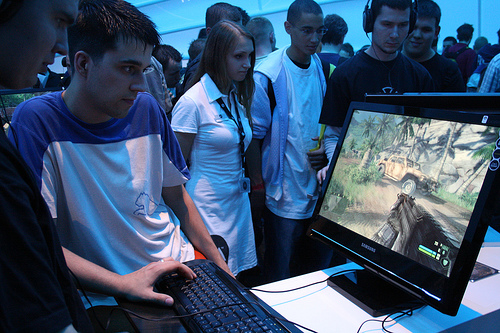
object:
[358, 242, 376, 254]
samsung logo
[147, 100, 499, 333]
computer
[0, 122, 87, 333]
black dress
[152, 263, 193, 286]
finger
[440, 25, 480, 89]
man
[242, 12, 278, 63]
man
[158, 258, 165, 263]
ring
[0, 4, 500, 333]
crowd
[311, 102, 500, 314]
video game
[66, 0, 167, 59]
hair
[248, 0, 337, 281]
people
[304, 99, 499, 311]
screen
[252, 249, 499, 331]
whitedesk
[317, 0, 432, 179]
boy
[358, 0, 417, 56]
head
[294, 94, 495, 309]
game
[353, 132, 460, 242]
fps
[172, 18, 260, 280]
girl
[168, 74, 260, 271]
dress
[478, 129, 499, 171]
stickers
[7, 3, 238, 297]
guy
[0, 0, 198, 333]
man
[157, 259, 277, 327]
keyboard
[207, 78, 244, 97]
neck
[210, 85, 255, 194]
tag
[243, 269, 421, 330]
wires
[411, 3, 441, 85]
person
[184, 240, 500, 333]
desk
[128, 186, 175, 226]
logo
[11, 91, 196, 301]
shirt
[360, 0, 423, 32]
headphones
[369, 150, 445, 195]
jeep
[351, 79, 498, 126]
computer monitor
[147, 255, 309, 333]
keyboard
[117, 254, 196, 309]
hand